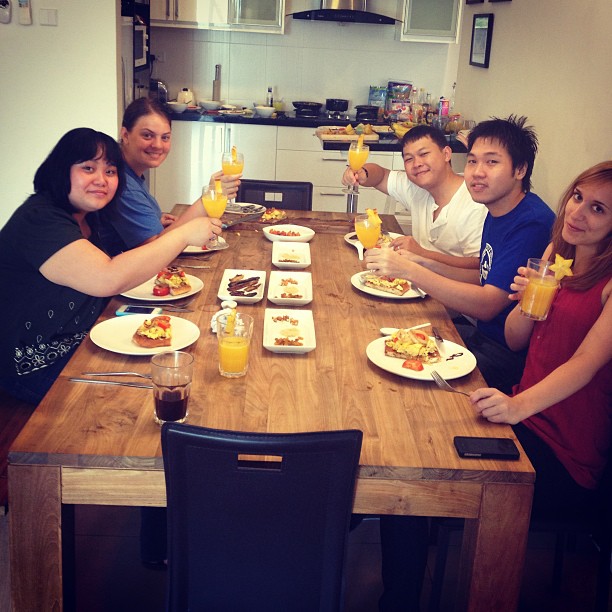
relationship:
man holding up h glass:
[350, 126, 483, 266] [344, 141, 368, 181]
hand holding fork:
[470, 385, 516, 428] [429, 366, 471, 400]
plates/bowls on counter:
[162, 93, 301, 125] [148, 103, 300, 127]